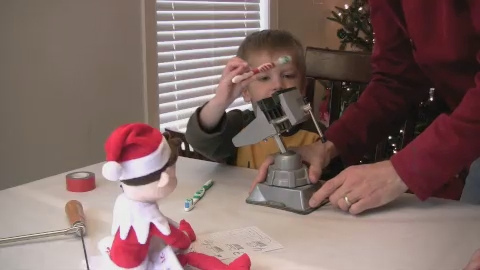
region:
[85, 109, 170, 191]
red hat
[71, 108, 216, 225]
red hat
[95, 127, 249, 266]
a plush elf doll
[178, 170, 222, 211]
a green and white toothbrush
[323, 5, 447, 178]
a lit Christmas tree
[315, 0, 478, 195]
a dark red blouse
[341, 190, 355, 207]
a gold wedding band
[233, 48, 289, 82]
a red white and green toothbrush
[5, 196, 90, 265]
a wooden hack saw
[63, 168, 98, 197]
a roll of red tape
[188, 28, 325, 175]
a young boy at table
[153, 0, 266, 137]
white venetian blinds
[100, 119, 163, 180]
red and white santa hat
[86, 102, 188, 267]
santa stuff toy